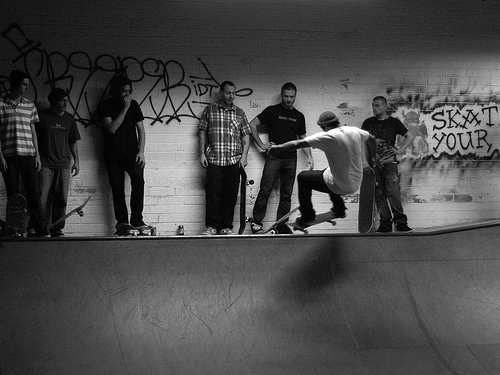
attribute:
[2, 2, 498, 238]
wall — white , brick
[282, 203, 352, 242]
skateboard — black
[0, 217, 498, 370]
ramp — grey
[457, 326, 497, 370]
patch — Dark , grey 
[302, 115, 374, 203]
shirt — man's , white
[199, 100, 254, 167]
shirt — plaid, man's 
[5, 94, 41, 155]
shirt — man's , striped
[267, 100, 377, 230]
man — sktateboarding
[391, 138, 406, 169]
hand — mans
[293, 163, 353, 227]
pants — mans, black